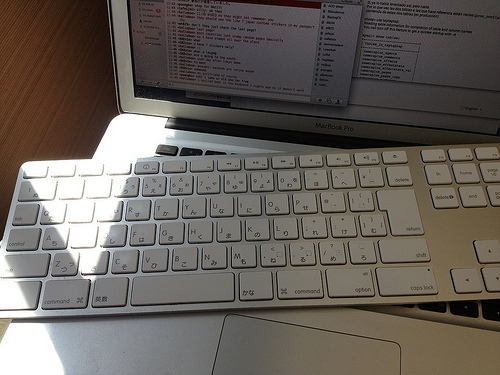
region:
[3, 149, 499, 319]
Silver and white keyboard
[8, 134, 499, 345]
Black letters on the keyboard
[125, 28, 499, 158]
White computer screen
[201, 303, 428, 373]
White mousepad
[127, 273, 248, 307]
White spacebar on keypad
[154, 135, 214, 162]
Two black buttons on keyboard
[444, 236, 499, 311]
Three directions buttons on keyboard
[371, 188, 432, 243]
Large enter button on keyboard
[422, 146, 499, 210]
9 keyboard buttons to the top right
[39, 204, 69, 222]
white key on keyboard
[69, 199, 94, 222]
white key on keyboard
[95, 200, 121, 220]
white key on keyboard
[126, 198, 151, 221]
white key on keyboard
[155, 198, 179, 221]
white key on keyboard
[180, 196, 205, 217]
white key on keyboard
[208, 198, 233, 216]
white key on keyboard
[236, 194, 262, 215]
white key on keyboard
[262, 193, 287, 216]
white key on keyboard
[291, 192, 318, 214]
white key on keyboard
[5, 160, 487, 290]
A white computer keyboard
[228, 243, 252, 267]
A white computer keyboard's letter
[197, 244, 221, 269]
A white computer keyboard's letter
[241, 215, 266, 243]
A white computer keyboard's letter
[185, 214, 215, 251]
A white computer keyboard's letter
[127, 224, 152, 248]
A white computer keyboard's letter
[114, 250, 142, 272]
A white computer keyboard's letter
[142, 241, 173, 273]
A white computer keyboard's letter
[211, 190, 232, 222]
A white computer keyboard's letter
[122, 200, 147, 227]
A white computer keyboard's letter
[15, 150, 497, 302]
the keyboard on the keyboard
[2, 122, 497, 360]
the keyboard on the laptop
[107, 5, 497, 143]
the laptop is on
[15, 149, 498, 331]
the keyboard is silver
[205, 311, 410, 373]
the trackpad of the laptop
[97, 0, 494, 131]
monitor of the laptop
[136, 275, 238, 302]
the spacebar of the laptop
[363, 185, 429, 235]
the return key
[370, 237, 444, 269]
the shift key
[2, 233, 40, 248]
the control key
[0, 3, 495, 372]
open laptop on table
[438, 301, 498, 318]
black buttons on keyboard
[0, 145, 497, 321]
keyboard on top of laptop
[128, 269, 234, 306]
long plain white button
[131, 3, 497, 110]
image on laptop screen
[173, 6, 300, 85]
black words on white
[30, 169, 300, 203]
row of number keys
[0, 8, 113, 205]
wood surface of table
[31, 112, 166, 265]
light reflection on keyboards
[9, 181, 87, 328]
shadow on keyboard buttons